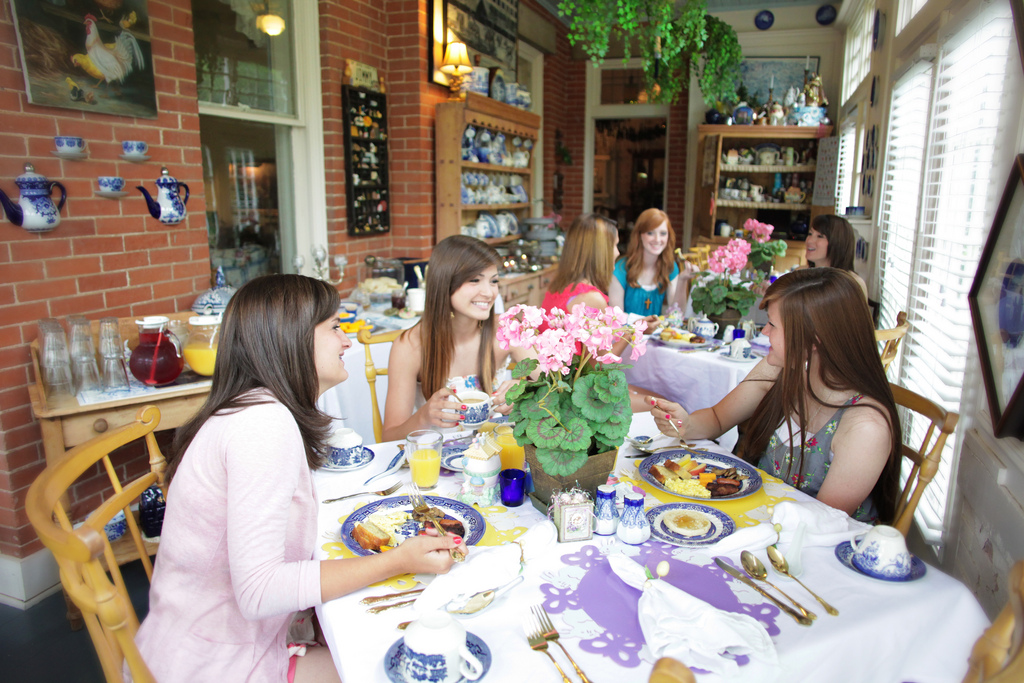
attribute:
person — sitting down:
[626, 263, 912, 533]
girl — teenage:
[109, 269, 468, 675]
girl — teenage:
[370, 226, 527, 442]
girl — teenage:
[637, 260, 913, 526]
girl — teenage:
[532, 206, 627, 336]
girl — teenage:
[608, 204, 691, 331]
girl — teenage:
[788, 210, 866, 287]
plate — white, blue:
[633, 434, 761, 512]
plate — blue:
[332, 484, 488, 577]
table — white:
[320, 364, 973, 674]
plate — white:
[639, 491, 747, 550]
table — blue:
[248, 392, 982, 680]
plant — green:
[481, 291, 652, 525]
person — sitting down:
[95, 266, 469, 677]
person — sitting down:
[359, 229, 556, 448]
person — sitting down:
[643, 256, 918, 529]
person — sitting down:
[769, 212, 865, 296]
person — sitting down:
[529, 207, 651, 385]